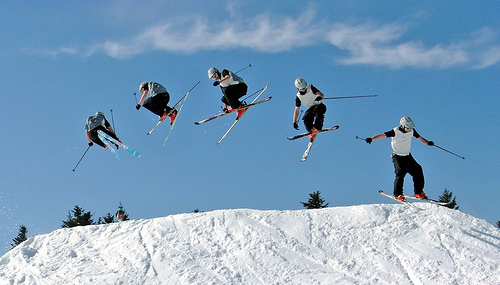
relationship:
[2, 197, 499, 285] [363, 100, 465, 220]
snow below man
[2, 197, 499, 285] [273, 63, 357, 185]
snow under man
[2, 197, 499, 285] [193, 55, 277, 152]
snow under man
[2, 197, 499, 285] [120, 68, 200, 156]
snow under man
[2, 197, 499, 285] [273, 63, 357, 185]
snow below man